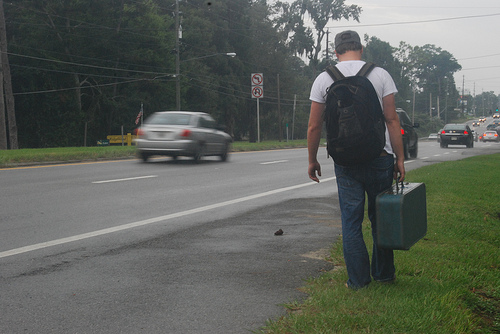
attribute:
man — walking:
[305, 31, 405, 291]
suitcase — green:
[373, 180, 430, 251]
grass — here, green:
[261, 150, 499, 333]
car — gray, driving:
[133, 108, 233, 163]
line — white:
[2, 158, 418, 259]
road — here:
[1, 114, 497, 276]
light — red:
[181, 127, 192, 138]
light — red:
[132, 128, 144, 138]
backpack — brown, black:
[325, 59, 385, 168]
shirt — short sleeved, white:
[309, 60, 400, 159]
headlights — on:
[471, 122, 482, 125]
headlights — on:
[477, 118, 487, 123]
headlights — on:
[492, 115, 500, 119]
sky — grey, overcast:
[261, 2, 500, 93]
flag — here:
[134, 105, 144, 126]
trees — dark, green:
[2, 0, 297, 149]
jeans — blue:
[332, 152, 398, 286]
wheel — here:
[137, 153, 155, 163]